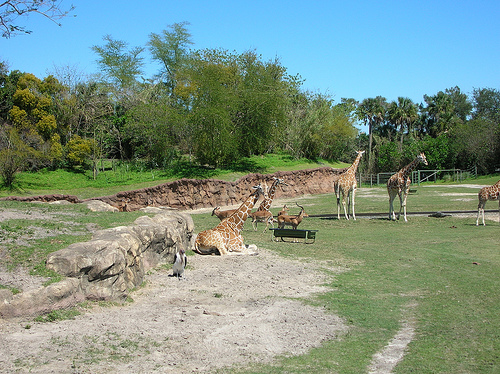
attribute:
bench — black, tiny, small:
[272, 222, 320, 248]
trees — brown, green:
[7, 30, 494, 171]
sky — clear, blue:
[4, 3, 497, 103]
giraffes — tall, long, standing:
[197, 149, 499, 256]